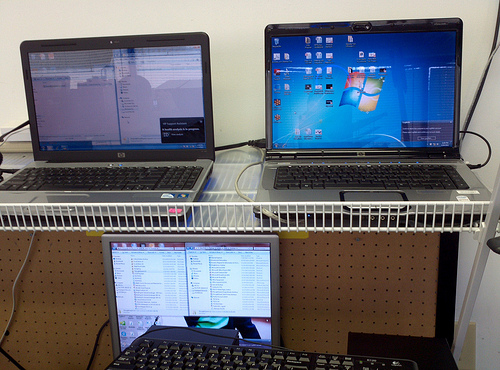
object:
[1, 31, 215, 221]
laptop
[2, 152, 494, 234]
shelf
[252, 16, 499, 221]
laptop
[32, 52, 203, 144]
background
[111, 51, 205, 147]
windows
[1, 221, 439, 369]
pegboard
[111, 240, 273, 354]
screen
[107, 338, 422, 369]
keyboard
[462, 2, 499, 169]
cord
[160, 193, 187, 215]
stickers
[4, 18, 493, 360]
computers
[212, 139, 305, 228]
wires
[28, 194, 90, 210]
mouse pad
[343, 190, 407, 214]
mouse pad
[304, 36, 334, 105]
icons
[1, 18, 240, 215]
laptops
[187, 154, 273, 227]
plastic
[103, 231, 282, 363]
monitor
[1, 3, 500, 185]
wall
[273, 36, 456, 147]
screen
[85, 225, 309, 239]
tape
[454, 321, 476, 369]
switch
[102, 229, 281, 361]
laptop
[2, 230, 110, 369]
wire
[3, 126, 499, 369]
display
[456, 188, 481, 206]
labels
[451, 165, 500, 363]
pole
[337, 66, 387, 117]
logo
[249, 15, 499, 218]
desktop